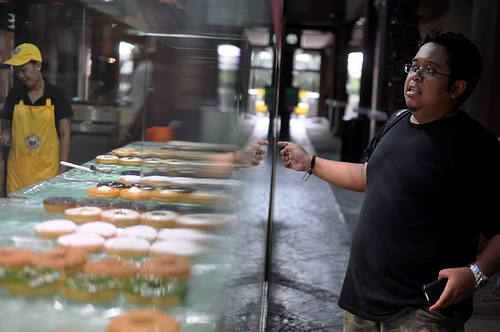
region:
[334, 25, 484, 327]
this is a man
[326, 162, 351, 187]
the man is light skinned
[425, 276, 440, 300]
this is a phone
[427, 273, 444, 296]
the phone is black in color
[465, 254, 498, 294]
this is a watch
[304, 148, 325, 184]
this is a wrist band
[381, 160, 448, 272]
this is a t shirt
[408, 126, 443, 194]
the t shirt is black in color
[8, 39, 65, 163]
this is a lady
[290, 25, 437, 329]
this is a man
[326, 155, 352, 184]
the man is light skinned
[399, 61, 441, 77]
this is a spectacle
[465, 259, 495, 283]
this is a watch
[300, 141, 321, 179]
this is a wrist band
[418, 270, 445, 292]
this is a phone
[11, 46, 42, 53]
the cap is yellow in color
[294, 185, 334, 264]
this is the ground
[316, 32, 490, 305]
this is a man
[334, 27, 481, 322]
the man is fat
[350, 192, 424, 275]
this is the belly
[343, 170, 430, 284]
the belly is fat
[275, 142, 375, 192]
this is the hand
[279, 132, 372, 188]
the hand is short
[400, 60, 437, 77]
he is wearing spectacles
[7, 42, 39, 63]
this is a cap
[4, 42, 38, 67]
the cap is yellow in color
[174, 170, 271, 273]
this is a glass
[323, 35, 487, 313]
this is a man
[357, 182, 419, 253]
this is the belly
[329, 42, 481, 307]
the man is fat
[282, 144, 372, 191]
the hand is short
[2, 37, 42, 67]
this is a cap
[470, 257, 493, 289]
this is a wrist watch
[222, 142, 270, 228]
this is a glass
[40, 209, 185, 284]
these are queen cakes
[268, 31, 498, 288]
the man is ordering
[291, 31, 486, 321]
the man is pointing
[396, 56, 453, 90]
the man wearing glasses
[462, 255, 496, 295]
the watch on the wrist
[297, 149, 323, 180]
the band on the wrist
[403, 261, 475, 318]
the man holding the phone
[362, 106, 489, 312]
the man wearing black t shirt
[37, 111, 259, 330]
the donuts on display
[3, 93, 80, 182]
person wearing yellow apron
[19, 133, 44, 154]
logo on the apron